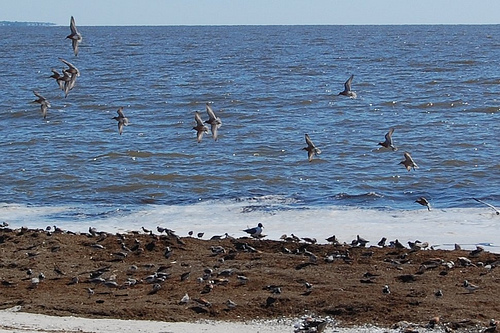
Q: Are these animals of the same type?
A: Yes, all the animals are birds.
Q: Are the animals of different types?
A: No, all the animals are birds.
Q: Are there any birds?
A: Yes, there is a bird.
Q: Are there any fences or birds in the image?
A: Yes, there is a bird.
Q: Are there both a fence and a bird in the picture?
A: No, there is a bird but no fences.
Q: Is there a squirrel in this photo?
A: No, there are no squirrels.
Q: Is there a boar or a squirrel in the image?
A: No, there are no squirrels or boars.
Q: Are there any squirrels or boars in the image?
A: No, there are no squirrels or boars.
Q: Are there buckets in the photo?
A: No, there are no buckets.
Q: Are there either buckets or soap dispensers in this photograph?
A: No, there are no buckets or soap dispensers.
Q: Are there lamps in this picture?
A: No, there are no lamps.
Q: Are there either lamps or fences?
A: No, there are no lamps or fences.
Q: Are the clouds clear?
A: Yes, the clouds are clear.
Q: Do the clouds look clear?
A: Yes, the clouds are clear.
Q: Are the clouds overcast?
A: No, the clouds are clear.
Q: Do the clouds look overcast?
A: No, the clouds are clear.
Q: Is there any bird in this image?
A: Yes, there is a bird.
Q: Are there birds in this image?
A: Yes, there is a bird.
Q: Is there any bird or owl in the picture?
A: Yes, there is a bird.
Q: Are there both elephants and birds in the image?
A: No, there is a bird but no elephants.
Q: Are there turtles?
A: No, there are no turtles.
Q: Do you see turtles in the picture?
A: No, there are no turtles.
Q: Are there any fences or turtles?
A: No, there are no turtles or fences.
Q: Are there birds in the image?
A: Yes, there are birds.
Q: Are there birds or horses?
A: Yes, there are birds.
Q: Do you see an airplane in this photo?
A: No, there are no airplanes.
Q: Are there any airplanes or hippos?
A: No, there are no airplanes or hippos.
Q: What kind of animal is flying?
A: The animal is birds.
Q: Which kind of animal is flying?
A: The animal is birds.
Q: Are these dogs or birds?
A: These are birds.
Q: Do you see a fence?
A: No, there are no fences.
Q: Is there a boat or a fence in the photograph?
A: No, there are no fences or boats.